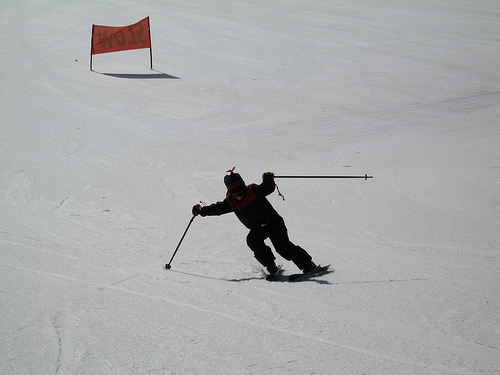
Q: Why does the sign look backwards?
A: We're behind it.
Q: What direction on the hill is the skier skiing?
A: Downward.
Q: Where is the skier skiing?
A: Down a slope.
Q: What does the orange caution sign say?
A: Slow.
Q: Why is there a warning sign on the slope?
A: To warn people.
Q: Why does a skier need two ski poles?
A: For control.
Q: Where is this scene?
A: Ski slope.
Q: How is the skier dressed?
A: Black.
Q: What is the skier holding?
A: Poles.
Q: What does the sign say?
A: Slow.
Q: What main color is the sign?
A: Orange.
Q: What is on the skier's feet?
A: Skis.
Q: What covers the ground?
A: Snow.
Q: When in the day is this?
A: Early evening.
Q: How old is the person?
A: Adult.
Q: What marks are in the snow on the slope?
A: Ski marks.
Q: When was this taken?
A: Daytime.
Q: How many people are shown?
A: 1.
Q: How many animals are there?
A: 0.